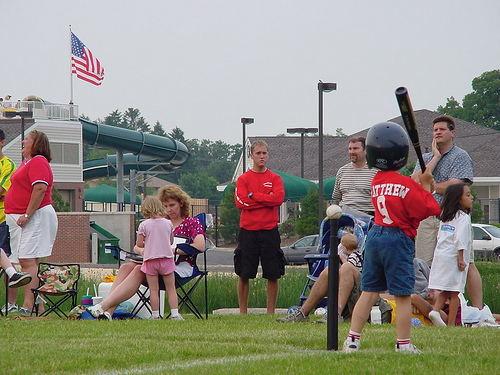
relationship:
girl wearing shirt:
[135, 195, 186, 320] [135, 217, 176, 261]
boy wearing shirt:
[232, 139, 286, 317] [232, 169, 286, 230]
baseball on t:
[325, 202, 342, 221] [327, 218, 340, 352]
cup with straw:
[80, 295, 96, 319] [85, 284, 90, 295]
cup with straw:
[93, 294, 102, 304] [92, 281, 98, 295]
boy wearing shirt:
[342, 122, 441, 356] [370, 168, 442, 239]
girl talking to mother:
[135, 195, 186, 320] [85, 182, 209, 318]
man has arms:
[234, 137, 286, 318] [234, 171, 286, 210]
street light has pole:
[315, 80, 340, 94] [316, 89, 324, 228]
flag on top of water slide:
[68, 30, 106, 87] [80, 119, 189, 179]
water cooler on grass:
[96, 278, 167, 321] [1, 312, 499, 374]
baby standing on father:
[335, 232, 377, 323] [273, 255, 450, 327]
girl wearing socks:
[425, 181, 472, 328] [426, 307, 452, 331]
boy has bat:
[342, 122, 441, 356] [392, 83, 436, 197]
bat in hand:
[392, 83, 436, 197] [418, 166, 435, 184]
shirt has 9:
[370, 168, 442, 239] [375, 193, 397, 229]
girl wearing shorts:
[135, 195, 186, 320] [141, 256, 177, 276]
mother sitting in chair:
[85, 182, 209, 318] [116, 213, 212, 320]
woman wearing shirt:
[6, 129, 63, 316] [4, 154, 55, 216]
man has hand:
[409, 114, 474, 277] [429, 137, 443, 159]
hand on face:
[429, 137, 443, 159] [432, 121, 450, 144]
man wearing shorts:
[234, 137, 286, 318] [232, 226, 288, 281]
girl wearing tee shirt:
[425, 181, 472, 328] [425, 212, 472, 292]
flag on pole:
[68, 30, 106, 87] [65, 20, 75, 118]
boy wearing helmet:
[342, 122, 441, 356] [361, 119, 412, 170]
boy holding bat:
[342, 122, 441, 356] [392, 83, 436, 197]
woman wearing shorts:
[6, 129, 63, 316] [3, 205, 61, 259]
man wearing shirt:
[234, 137, 286, 318] [232, 169, 286, 230]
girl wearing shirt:
[425, 181, 472, 328] [428, 209, 474, 297]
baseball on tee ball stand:
[325, 202, 342, 221] [327, 218, 340, 352]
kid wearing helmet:
[342, 122, 441, 356] [361, 119, 412, 170]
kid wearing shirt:
[342, 122, 441, 356] [370, 168, 442, 239]